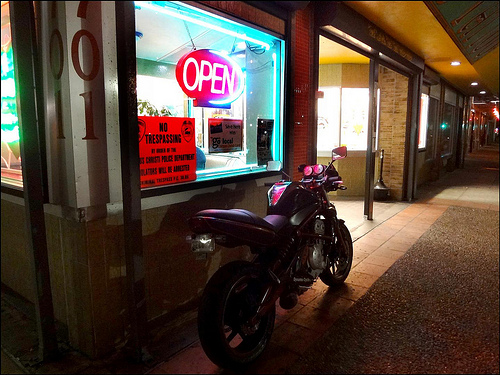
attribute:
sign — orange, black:
[138, 115, 197, 190]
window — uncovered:
[319, 82, 380, 152]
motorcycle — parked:
[179, 136, 368, 369]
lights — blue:
[415, 111, 483, 151]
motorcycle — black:
[186, 146, 352, 368]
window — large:
[134, 0, 284, 190]